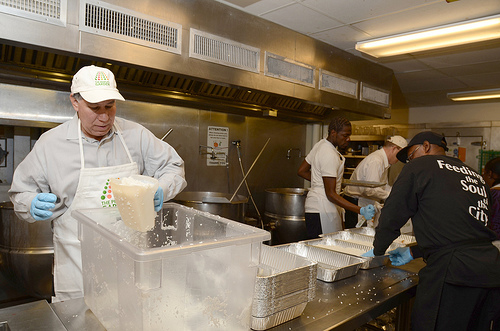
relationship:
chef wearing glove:
[8, 65, 188, 304] [20, 191, 58, 224]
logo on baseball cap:
[91, 67, 111, 88] [70, 65, 126, 104]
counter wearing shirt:
[1, 237, 421, 329] [372, 154, 492, 263]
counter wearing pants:
[1, 237, 421, 329] [410, 241, 499, 330]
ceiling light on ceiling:
[354, 15, 500, 60] [215, 0, 499, 120]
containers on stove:
[264, 186, 309, 245] [246, 210, 324, 247]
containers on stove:
[173, 191, 248, 241] [246, 210, 324, 247]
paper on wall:
[207, 125, 229, 166] [1, 81, 306, 220]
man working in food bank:
[361, 130, 500, 331] [2, 1, 498, 331]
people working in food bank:
[340, 132, 415, 221] [2, 1, 498, 331]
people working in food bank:
[294, 118, 362, 232] [2, 1, 498, 331]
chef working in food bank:
[8, 65, 188, 304] [2, 1, 498, 331]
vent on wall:
[356, 81, 391, 107] [2, 1, 399, 121]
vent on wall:
[319, 67, 358, 102] [2, 1, 399, 121]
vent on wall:
[265, 51, 318, 96] [2, 1, 399, 121]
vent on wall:
[184, 21, 261, 78] [2, 1, 399, 121]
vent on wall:
[82, 0, 188, 54] [2, 1, 399, 121]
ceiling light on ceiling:
[354, 15, 500, 60] [316, 3, 485, 72]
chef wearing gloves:
[8, 65, 188, 304] [27, 181, 169, 226]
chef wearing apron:
[8, 65, 188, 304] [53, 120, 149, 300]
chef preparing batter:
[10, 49, 242, 324] [107, 173, 161, 233]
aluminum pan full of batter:
[298, 237, 390, 270] [307, 229, 402, 276]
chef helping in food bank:
[8, 65, 188, 304] [2, 1, 498, 326]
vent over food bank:
[319, 67, 358, 102] [2, 1, 498, 331]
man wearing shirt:
[368, 122, 496, 329] [373, 155, 500, 289]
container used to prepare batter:
[74, 188, 274, 329] [90, 153, 189, 243]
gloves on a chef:
[21, 191, 168, 218] [8, 65, 188, 304]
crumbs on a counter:
[331, 279, 394, 311] [1, 220, 438, 329]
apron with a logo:
[48, 120, 150, 300] [98, 176, 117, 205]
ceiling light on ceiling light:
[354, 15, 500, 60] [444, 88, 499, 101]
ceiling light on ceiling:
[354, 15, 500, 60] [318, 0, 419, 39]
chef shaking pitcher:
[8, 65, 188, 304] [111, 172, 162, 232]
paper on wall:
[200, 123, 230, 166] [185, 111, 306, 186]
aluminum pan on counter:
[273, 241, 370, 285] [1, 237, 421, 329]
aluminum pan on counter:
[312, 235, 372, 262] [1, 237, 421, 329]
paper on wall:
[207, 125, 229, 166] [188, 119, 290, 191]